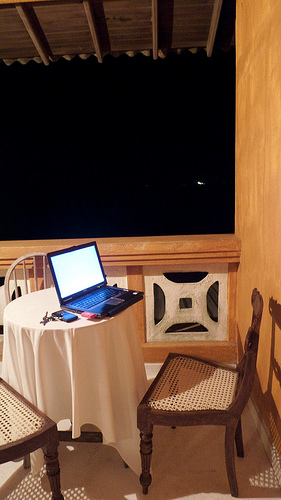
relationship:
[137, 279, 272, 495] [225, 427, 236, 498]
chair has leg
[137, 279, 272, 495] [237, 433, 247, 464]
chair has leg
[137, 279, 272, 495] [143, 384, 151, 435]
chair has leg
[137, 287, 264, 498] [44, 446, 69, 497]
chair has leg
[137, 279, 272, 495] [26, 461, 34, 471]
chair has leg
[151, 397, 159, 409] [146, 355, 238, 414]
hole in seat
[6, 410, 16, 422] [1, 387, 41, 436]
hole in seat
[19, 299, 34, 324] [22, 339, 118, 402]
table with cloth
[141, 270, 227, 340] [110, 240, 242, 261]
design under railing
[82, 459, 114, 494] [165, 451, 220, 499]
shadow on floor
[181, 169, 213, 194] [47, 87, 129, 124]
light in dark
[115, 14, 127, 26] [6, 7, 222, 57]
red on roof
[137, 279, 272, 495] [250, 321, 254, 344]
chair made of wood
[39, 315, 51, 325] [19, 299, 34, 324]
keys on table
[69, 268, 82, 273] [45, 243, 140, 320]
screen on laptop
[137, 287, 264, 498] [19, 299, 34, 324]
chair around table